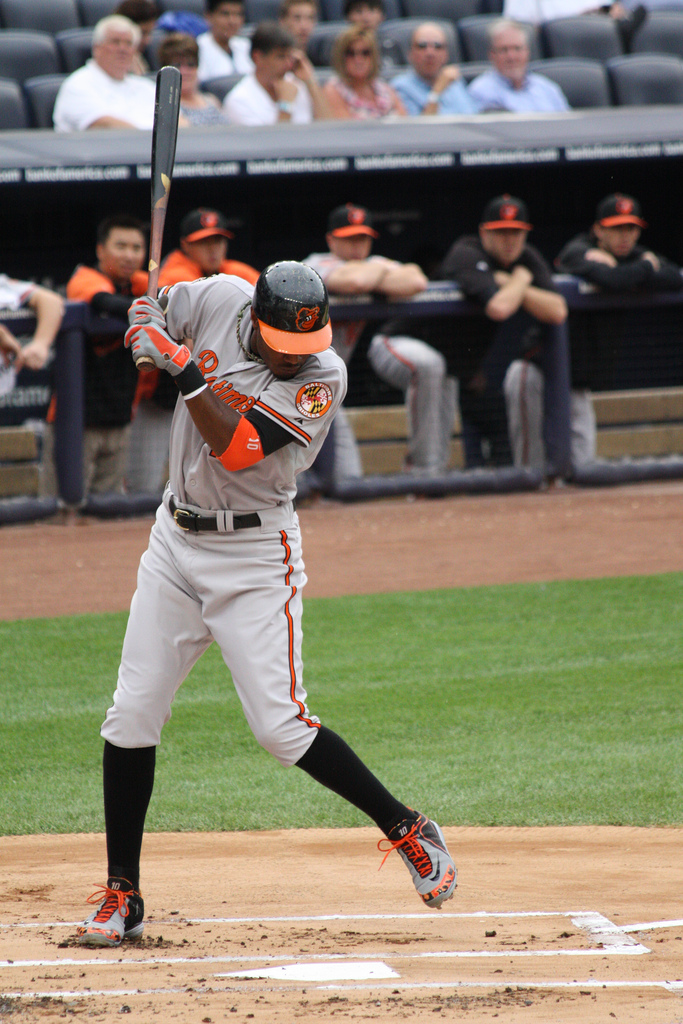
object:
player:
[37, 215, 149, 495]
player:
[124, 207, 261, 494]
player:
[301, 203, 429, 477]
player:
[367, 194, 569, 479]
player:
[503, 193, 683, 466]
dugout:
[0, 139, 683, 523]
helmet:
[252, 261, 332, 355]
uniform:
[368, 237, 567, 474]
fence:
[0, 272, 683, 496]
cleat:
[377, 806, 458, 910]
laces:
[377, 821, 432, 878]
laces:
[87, 883, 133, 923]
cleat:
[76, 877, 144, 947]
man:
[388, 20, 479, 117]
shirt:
[389, 64, 479, 115]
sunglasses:
[411, 41, 446, 49]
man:
[52, 13, 190, 133]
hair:
[91, 14, 142, 49]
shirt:
[52, 57, 184, 132]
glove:
[124, 322, 191, 376]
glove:
[127, 296, 167, 329]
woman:
[323, 19, 408, 120]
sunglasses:
[345, 48, 371, 57]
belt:
[169, 495, 297, 532]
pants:
[99, 480, 321, 768]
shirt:
[158, 273, 349, 511]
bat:
[136, 66, 182, 373]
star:
[154, 172, 171, 210]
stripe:
[279, 529, 321, 729]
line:
[0, 911, 608, 928]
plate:
[208, 961, 402, 982]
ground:
[0, 481, 683, 1024]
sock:
[103, 739, 156, 894]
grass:
[0, 569, 683, 836]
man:
[77, 261, 458, 947]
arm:
[175, 348, 348, 471]